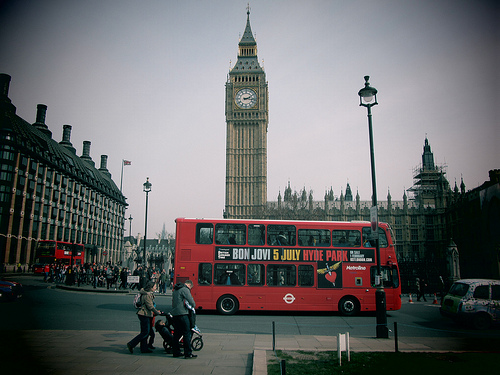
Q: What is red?
A: Bus.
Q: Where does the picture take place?
A: London.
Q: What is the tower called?
A: Big Ben.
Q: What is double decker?
A: A bus.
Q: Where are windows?
A: On a bus.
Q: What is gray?
A: Sky.